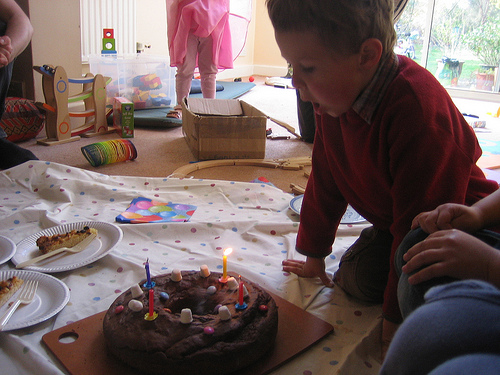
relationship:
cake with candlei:
[102, 268, 278, 373] [145, 258, 151, 285]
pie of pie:
[36, 226, 97, 254] [36, 223, 95, 254]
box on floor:
[174, 88, 272, 158] [19, 83, 498, 202]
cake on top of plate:
[102, 268, 278, 373] [34, 268, 336, 374]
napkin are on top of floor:
[115, 197, 197, 224] [19, 83, 498, 202]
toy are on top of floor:
[81, 139, 138, 167] [19, 83, 498, 202]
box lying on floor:
[174, 88, 272, 158] [19, 83, 498, 202]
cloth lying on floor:
[2, 160, 386, 374] [19, 83, 498, 202]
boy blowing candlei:
[260, 1, 498, 298] [145, 258, 151, 285]